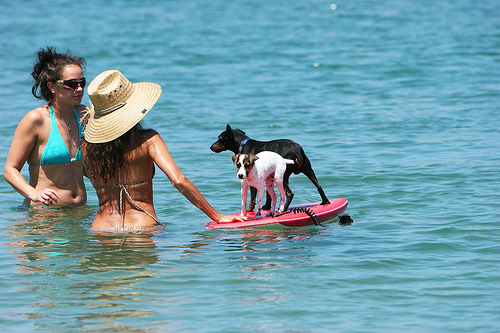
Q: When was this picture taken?
A: During the day.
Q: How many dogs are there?
A: Two.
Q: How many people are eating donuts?
A: Zero.